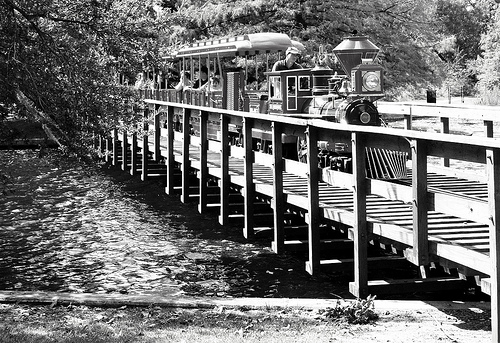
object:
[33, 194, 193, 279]
water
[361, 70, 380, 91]
light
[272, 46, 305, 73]
guy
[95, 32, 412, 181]
train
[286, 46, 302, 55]
hat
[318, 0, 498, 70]
trees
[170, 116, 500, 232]
track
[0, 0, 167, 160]
trees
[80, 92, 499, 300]
bridge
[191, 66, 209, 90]
people